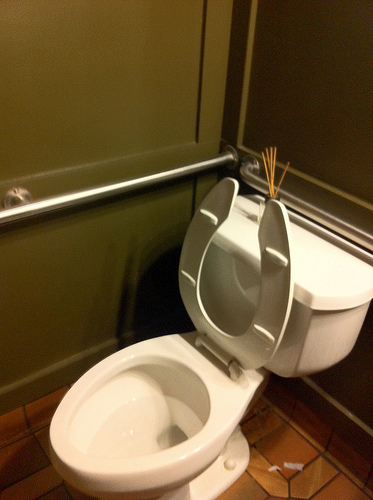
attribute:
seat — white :
[170, 170, 301, 377]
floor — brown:
[253, 441, 329, 498]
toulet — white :
[34, 203, 323, 496]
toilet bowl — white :
[40, 332, 261, 499]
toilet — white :
[57, 170, 363, 497]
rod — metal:
[1, 148, 245, 235]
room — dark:
[0, 2, 371, 498]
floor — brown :
[4, 335, 371, 498]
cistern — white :
[197, 191, 369, 378]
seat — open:
[160, 187, 327, 358]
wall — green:
[276, 31, 370, 147]